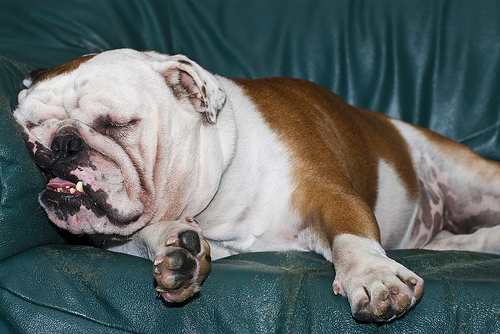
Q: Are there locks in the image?
A: No, there are no locks.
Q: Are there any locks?
A: No, there are no locks.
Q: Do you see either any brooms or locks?
A: No, there are no locks or brooms.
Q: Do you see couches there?
A: Yes, there is a couch.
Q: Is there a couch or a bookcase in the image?
A: Yes, there is a couch.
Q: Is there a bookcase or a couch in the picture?
A: Yes, there is a couch.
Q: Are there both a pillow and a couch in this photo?
A: No, there is a couch but no pillows.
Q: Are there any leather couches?
A: Yes, there is a couch that is made of leather.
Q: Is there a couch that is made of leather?
A: Yes, there is a couch that is made of leather.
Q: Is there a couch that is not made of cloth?
A: Yes, there is a couch that is made of leather.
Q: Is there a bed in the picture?
A: No, there are no beds.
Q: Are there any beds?
A: No, there are no beds.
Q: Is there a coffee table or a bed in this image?
A: No, there are no beds or coffee tables.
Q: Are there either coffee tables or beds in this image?
A: No, there are no beds or coffee tables.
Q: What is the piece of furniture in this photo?
A: The piece of furniture is a couch.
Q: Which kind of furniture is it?
A: The piece of furniture is a couch.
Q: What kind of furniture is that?
A: That is a couch.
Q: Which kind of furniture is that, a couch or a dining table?
A: That is a couch.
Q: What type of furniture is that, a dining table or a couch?
A: That is a couch.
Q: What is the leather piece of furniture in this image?
A: The piece of furniture is a couch.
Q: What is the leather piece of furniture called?
A: The piece of furniture is a couch.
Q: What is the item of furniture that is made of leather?
A: The piece of furniture is a couch.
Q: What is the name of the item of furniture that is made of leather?
A: The piece of furniture is a couch.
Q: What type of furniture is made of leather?
A: The furniture is a couch.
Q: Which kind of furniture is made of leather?
A: The furniture is a couch.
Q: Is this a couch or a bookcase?
A: This is a couch.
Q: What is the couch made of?
A: The couch is made of leather.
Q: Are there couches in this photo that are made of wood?
A: No, there is a couch but it is made of leather.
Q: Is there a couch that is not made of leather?
A: No, there is a couch but it is made of leather.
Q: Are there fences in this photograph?
A: No, there are no fences.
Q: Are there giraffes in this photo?
A: No, there are no giraffes.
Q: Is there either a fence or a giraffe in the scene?
A: No, there are no giraffes or fences.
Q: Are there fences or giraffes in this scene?
A: No, there are no giraffes or fences.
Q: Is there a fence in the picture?
A: No, there are no fences.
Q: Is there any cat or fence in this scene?
A: No, there are no fences or cats.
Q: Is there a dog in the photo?
A: Yes, there is a dog.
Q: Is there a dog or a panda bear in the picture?
A: Yes, there is a dog.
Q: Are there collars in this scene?
A: No, there are no collars.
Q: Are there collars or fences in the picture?
A: No, there are no collars or fences.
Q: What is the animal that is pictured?
A: The animal is a dog.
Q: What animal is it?
A: The animal is a dog.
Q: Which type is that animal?
A: This is a dog.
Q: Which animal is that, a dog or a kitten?
A: This is a dog.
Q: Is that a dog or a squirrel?
A: That is a dog.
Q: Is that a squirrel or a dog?
A: That is a dog.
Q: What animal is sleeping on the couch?
A: The dog is sleeping on the couch.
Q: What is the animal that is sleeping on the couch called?
A: The animal is a dog.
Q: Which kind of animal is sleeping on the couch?
A: The animal is a dog.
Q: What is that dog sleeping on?
A: The dog is sleeping on the couch.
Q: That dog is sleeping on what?
A: The dog is sleeping on the couch.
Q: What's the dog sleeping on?
A: The dog is sleeping on the couch.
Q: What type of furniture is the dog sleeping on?
A: The dog is sleeping on the couch.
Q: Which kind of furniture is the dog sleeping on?
A: The dog is sleeping on the couch.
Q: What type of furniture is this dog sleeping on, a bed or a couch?
A: The dog is sleeping on a couch.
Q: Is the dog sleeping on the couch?
A: Yes, the dog is sleeping on the couch.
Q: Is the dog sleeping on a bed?
A: No, the dog is sleeping on the couch.